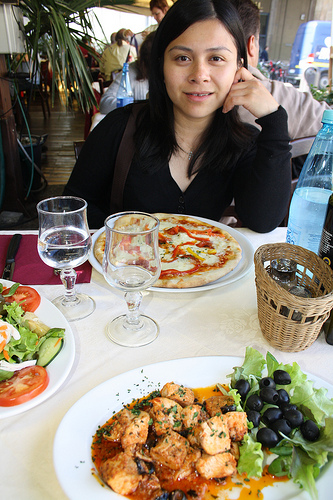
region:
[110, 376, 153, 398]
green herb on plate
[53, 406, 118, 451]
edge of white plate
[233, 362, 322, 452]
black olives on plate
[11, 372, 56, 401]
slice of juicy red tomato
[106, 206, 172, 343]
shiny clear wine glass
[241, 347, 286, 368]
crisp green lettuce on plate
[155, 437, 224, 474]
delicious chicken in sauce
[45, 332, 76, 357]
sliver of orange carrot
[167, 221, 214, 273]
red and yellow peppers on pizza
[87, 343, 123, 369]
line on white tablecloth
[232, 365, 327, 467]
several black olives on a plate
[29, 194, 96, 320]
half filled glass of water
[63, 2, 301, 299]
woman eating at a restaurant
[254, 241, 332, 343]
basket of salt and pepper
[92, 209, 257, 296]
personal sized pizza at a restaurant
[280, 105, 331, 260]
bottle of water on a restaurant table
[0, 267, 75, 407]
salad with tomato, carrots, and cucumbers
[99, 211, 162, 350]
empty glass on the table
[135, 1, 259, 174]
woman with black hair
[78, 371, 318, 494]
seasoned chicken, black olives, and lettuce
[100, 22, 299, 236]
a woman in a black shirt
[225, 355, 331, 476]
lettuce and black olives on a plate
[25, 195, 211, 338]
two water glasses on the table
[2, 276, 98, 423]
salad on a plate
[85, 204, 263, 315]
pizza on a plate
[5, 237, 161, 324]
maroon napkin on the table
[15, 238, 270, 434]
three white plates on a table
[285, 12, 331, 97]
bus in the background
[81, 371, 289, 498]
a chicken dish on the plate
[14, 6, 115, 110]
green plant in the background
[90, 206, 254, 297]
white plate with pizza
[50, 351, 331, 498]
Chicken dish with salad and black olives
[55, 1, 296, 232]
woman posing for camera at restaurant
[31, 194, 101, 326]
Clear glass with water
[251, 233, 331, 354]
brown wicker basket with salt and pepper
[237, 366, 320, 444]
black olives on bed of lettuce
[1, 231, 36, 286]
red napkin with knife on table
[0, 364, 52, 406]
red tomato on plate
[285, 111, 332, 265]
bottle of water on table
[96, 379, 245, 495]
chicken in red sauce and green herbs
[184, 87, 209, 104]
the ladies gap tooth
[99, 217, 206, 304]
the pizza on the table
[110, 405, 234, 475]
the chicken on the table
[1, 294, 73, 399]
the salad on the table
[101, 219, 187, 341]
the empty glass on the table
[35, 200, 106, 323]
the half full glass on the table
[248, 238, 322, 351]
the basket on the table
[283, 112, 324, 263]
the bottle of water on the table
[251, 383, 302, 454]
the olives on the lettuce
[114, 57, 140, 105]
the bottle of water in the background